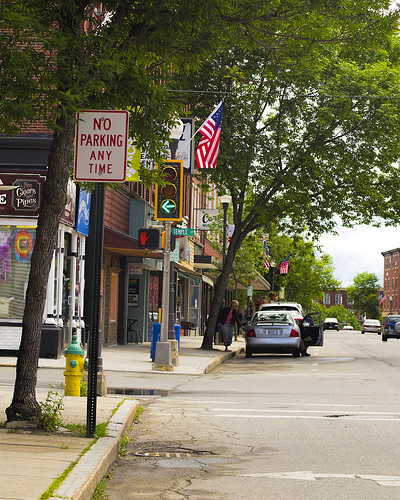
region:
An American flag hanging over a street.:
[184, 97, 240, 174]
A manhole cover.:
[122, 435, 219, 463]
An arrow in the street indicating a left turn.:
[232, 431, 393, 495]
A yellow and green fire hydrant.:
[55, 328, 91, 396]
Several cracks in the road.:
[148, 398, 229, 443]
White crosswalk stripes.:
[130, 382, 392, 433]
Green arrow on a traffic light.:
[144, 172, 193, 223]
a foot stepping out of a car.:
[239, 289, 332, 363]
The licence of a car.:
[258, 321, 292, 341]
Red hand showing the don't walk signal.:
[132, 223, 166, 252]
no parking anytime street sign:
[66, 105, 132, 186]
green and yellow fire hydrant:
[54, 328, 88, 398]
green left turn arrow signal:
[150, 153, 186, 230]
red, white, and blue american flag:
[167, 93, 232, 183]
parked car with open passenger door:
[240, 309, 329, 359]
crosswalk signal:
[131, 222, 161, 260]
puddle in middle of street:
[104, 376, 189, 408]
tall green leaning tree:
[192, 5, 396, 347]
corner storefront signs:
[0, 168, 92, 233]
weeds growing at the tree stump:
[31, 377, 69, 438]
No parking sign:
[35, 75, 162, 235]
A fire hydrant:
[65, 332, 99, 384]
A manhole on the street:
[147, 433, 227, 496]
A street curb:
[165, 341, 244, 421]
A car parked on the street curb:
[241, 301, 322, 387]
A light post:
[149, 324, 170, 348]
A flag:
[190, 103, 284, 207]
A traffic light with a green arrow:
[161, 159, 222, 276]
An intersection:
[154, 124, 192, 256]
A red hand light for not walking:
[130, 219, 160, 251]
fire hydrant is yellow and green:
[56, 347, 90, 405]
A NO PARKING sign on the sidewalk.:
[55, 106, 137, 454]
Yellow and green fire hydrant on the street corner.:
[53, 326, 95, 398]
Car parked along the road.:
[245, 304, 330, 361]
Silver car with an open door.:
[244, 300, 330, 360]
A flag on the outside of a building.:
[373, 290, 394, 313]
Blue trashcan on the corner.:
[144, 316, 182, 366]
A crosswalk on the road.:
[144, 393, 398, 437]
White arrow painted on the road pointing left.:
[229, 460, 393, 497]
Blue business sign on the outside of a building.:
[76, 182, 94, 240]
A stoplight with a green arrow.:
[146, 148, 191, 381]